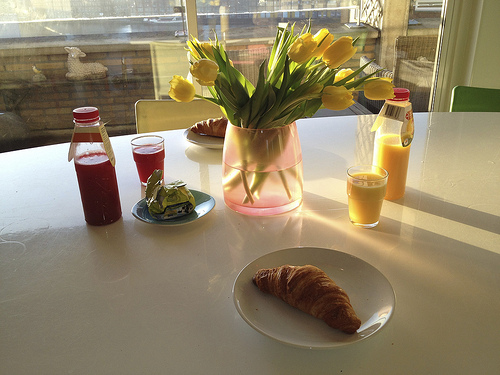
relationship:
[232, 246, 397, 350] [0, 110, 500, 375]
dish on ground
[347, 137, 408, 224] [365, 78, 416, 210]
orange juice in bottle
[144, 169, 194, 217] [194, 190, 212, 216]
wrapper on plate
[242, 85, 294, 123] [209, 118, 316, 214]
stems inside vase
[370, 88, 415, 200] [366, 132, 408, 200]
bottle holds orange juice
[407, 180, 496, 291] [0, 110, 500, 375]
shadows fall on ground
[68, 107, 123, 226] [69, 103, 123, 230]
bottle inside bottle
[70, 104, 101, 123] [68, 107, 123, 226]
red cap holds bottle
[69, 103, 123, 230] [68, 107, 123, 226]
bottle holds bottle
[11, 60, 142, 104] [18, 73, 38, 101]
wall made of brick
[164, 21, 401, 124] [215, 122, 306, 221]
flowers inside vase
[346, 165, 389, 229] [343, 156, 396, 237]
glass in glass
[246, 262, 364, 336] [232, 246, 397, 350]
croissant on dish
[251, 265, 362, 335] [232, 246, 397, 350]
croissant on dish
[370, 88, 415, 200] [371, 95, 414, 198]
bottle in bottle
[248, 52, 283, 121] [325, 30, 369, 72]
stem on flower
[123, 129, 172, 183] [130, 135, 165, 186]
glass has glass